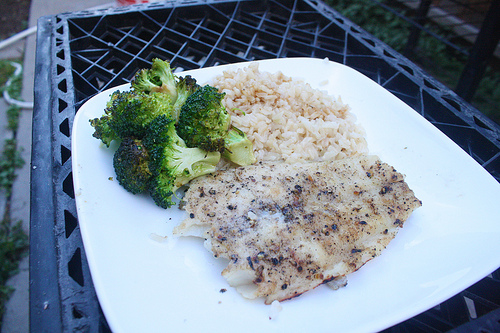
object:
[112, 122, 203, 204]
brocolli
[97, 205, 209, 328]
plate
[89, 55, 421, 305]
food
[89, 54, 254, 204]
broccoli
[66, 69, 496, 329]
plate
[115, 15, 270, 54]
rack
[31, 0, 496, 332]
crate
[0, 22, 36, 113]
hose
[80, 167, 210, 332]
plate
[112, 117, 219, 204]
broccoli piece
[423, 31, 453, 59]
bushes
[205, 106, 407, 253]
fish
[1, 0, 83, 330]
sidewalk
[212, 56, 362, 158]
rice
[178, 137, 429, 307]
chicken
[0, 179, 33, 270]
ground